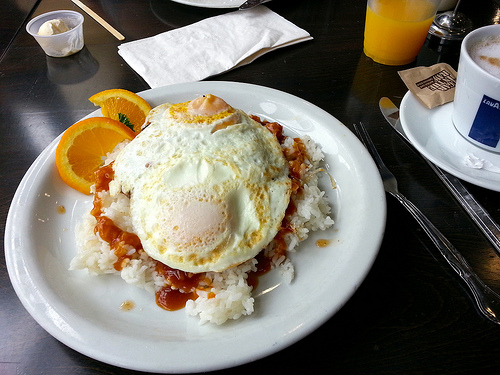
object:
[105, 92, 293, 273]
egg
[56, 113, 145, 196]
orange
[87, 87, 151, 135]
orange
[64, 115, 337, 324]
rice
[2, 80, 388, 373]
plate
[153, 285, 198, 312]
ketchup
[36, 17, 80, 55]
butter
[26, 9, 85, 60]
cup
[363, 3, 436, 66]
orange juice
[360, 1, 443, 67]
cup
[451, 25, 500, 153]
mug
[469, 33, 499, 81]
coffee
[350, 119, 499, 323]
fork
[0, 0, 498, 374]
table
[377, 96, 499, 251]
butter knife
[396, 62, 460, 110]
sugar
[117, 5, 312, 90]
napkin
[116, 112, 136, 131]
sprig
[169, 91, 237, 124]
yolk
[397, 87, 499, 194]
saucer